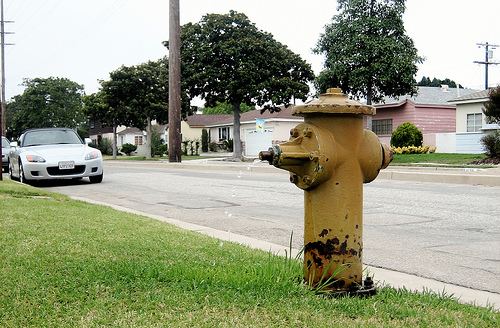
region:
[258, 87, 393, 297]
a yellow painted fire hydrant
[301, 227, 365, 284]
rust on a yellow fire hydrant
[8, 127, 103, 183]
a white sports car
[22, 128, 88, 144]
windshield of a white sports car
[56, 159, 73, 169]
license plate on a white sports car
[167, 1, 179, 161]
a wood electric pole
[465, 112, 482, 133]
window in a white house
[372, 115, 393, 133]
window in a pink house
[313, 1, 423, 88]
the top of a tall tree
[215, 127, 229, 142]
window in a yellow house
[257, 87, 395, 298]
beige fire hydrant in a neighborhood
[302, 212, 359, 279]
brown rust on beige fire hydrant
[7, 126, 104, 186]
white sports car parked beside the curb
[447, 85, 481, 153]
corner of blue and white house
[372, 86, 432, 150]
the corner of pink and white house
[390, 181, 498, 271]
asphalt on the street in the neighborhood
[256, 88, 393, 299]
fire hydrant next to the curb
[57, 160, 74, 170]
license plate on front of car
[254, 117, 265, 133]
blue flag on the side of white house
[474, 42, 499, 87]
utility pole behind the pink house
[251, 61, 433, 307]
a yellow fire hydrant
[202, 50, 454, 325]
an older fire hydrant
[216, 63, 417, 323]
a rusting fire hydrant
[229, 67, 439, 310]
a fire hydrant next to the street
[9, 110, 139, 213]
a silver vehicle parked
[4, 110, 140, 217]
a silver vehicle parked on the road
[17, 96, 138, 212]
a silver vehicle parked next to the grass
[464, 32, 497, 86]
a power pole in the distance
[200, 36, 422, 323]
a fire hydrant in the grass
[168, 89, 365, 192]
houses behind the fire hydrant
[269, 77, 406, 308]
yellow fire hydrant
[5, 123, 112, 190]
silver sports car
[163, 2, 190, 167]
wooden electrical pole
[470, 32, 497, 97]
pole holding up power lines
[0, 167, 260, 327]
edge of a grass lawn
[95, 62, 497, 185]
a line of houses next to the street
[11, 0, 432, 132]
green trees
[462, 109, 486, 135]
a window from outside a house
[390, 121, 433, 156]
a green bush with planted flowers around it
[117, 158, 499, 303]
a pavement street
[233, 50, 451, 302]
an old fire hydrant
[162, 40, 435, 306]
an old yellow fire hydrant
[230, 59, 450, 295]
a yellow fire hydrant next to the street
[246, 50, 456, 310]
a yellow fire hydrant in the grass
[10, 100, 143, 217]
a car parked in the street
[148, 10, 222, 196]
a tall wooden pole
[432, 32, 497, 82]
power lines in the distance